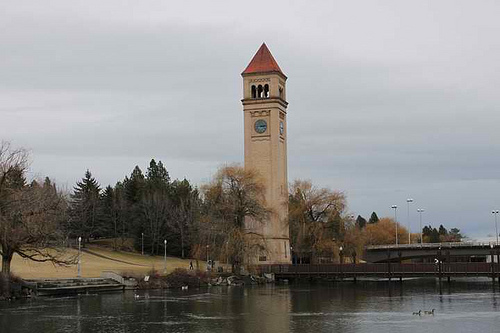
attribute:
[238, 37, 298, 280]
building — tall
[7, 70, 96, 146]
clouds — white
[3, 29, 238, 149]
sky — blue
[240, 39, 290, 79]
roof — orange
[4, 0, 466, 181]
sky — blue